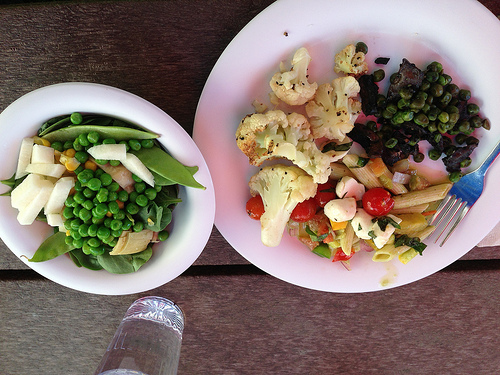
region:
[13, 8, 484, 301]
a white plate and a white bowl on a table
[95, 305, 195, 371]
a glass of water on a table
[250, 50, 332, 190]
steamed cauliflower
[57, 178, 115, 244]
a bunch of green peas in a bowl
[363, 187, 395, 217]
a cherry tomato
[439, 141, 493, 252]
a fork on a plate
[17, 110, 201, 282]
a bowl of veggies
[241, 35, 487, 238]
a plate of veggies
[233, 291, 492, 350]
a wood table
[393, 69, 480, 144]
baked green peas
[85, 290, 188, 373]
a drinking glass on the table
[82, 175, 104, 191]
a green pea in the bowl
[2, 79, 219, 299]
a white bowl of vegetables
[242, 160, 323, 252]
a piece of cauliflower on the plate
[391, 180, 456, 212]
a piece of pasta on the plate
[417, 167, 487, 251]
the tines of a fork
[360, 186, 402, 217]
a red tomato on the plate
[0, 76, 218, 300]
a white bowl on the table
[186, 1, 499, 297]
a white plate on the table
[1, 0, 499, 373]
a brown table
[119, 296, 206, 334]
beautiful edge of clear glass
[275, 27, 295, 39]
tiny black food particle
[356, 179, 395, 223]
shiny small red grape tomato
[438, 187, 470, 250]
silver fork in plate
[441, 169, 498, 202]
blue base of fork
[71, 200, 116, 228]
large amount of green peas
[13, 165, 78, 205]
small chunks of white cheese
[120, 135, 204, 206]
single unit of sugar snap peas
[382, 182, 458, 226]
piece of white pasta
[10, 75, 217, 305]
small white bowl of food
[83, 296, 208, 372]
glass of water on table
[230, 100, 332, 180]
cauliflower on a plate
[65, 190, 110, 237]
green peas in a bowl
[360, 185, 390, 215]
cherry tomato on a plate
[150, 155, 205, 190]
snap peas in a bowl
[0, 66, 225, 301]
white bowl with vegetables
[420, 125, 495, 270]
silver fork on a plate of food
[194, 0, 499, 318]
white plate with food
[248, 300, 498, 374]
wooden table under food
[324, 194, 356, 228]
mozzarella cheese on a plate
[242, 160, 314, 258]
A piece of cauliflower.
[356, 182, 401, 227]
A small tomato.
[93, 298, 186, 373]
A clear glass of drink.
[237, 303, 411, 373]
A wooden table.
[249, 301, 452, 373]
The wood table is brown.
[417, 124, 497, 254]
A fork to the right.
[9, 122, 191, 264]
A bowl with peas in it.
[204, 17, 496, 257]
A plate a different types of vegetables.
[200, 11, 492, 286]
A white plate.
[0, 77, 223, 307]
A white bowl.